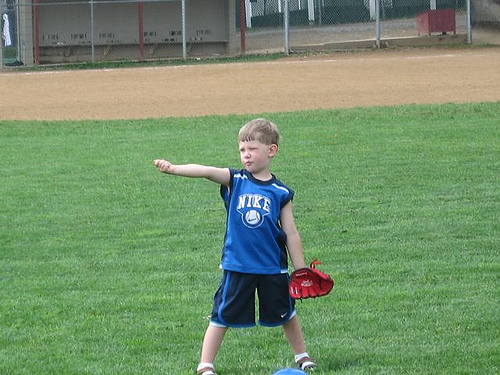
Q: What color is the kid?
A: White.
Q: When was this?
A: Daytime.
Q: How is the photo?
A: Clear.